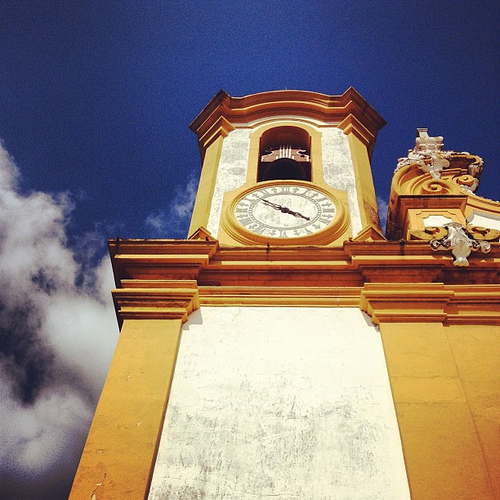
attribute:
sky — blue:
[195, 3, 485, 78]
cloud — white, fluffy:
[0, 147, 121, 499]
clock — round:
[223, 170, 355, 252]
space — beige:
[211, 351, 354, 473]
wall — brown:
[66, 317, 176, 499]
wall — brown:
[375, 315, 498, 492]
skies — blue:
[101, 31, 195, 79]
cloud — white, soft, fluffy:
[16, 265, 111, 373]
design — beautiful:
[322, 132, 351, 182]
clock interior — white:
[228, 183, 338, 238]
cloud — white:
[3, 368, 95, 493]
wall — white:
[142, 306, 412, 498]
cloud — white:
[1, 140, 87, 340]